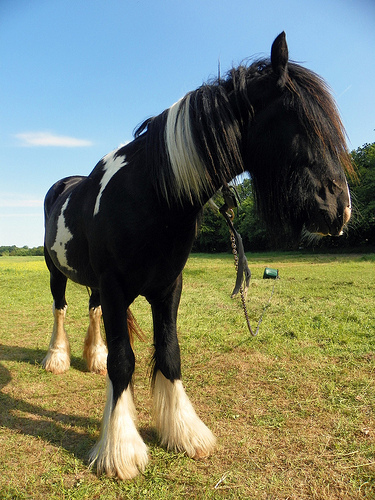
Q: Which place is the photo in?
A: It is at the field.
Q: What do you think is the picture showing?
A: It is showing a field.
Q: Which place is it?
A: It is a field.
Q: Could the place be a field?
A: Yes, it is a field.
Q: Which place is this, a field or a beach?
A: It is a field.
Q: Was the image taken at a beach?
A: No, the picture was taken in a field.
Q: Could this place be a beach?
A: No, it is a field.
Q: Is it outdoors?
A: Yes, it is outdoors.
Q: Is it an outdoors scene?
A: Yes, it is outdoors.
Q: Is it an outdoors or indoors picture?
A: It is outdoors.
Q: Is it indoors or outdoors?
A: It is outdoors.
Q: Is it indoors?
A: No, it is outdoors.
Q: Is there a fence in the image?
A: No, there are no fences.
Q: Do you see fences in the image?
A: No, there are no fences.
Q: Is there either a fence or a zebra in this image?
A: No, there are no fences or zebras.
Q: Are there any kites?
A: No, there are no kites.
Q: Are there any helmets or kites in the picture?
A: No, there are no kites or helmets.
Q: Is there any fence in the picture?
A: No, there are no fences.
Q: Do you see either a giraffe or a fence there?
A: No, there are no fences or giraffes.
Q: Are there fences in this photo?
A: No, there are no fences.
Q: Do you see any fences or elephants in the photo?
A: No, there are no fences or elephants.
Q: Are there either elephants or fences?
A: No, there are no fences or elephants.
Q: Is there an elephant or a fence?
A: No, there are no fences or elephants.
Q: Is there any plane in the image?
A: No, there are no airplanes.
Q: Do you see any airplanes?
A: No, there are no airplanes.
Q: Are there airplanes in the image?
A: No, there are no airplanes.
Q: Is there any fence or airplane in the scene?
A: No, there are no airplanes or fences.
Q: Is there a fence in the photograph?
A: No, there are no fences.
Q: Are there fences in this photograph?
A: No, there are no fences.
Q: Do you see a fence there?
A: No, there are no fences.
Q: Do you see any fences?
A: No, there are no fences.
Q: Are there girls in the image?
A: No, there are no girls.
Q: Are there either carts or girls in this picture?
A: No, there are no girls or carts.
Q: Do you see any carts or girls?
A: No, there are no girls or carts.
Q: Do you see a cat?
A: No, there are no cats.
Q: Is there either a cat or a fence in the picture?
A: No, there are no cats or fences.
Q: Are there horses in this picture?
A: Yes, there is a horse.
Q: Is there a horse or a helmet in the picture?
A: Yes, there is a horse.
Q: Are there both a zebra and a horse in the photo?
A: No, there is a horse but no zebras.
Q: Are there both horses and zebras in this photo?
A: No, there is a horse but no zebras.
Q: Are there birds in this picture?
A: No, there are no birds.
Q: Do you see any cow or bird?
A: No, there are no birds or cows.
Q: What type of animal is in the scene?
A: The animal is a horse.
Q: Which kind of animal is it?
A: The animal is a horse.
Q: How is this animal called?
A: This is a horse.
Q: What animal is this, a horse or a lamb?
A: This is a horse.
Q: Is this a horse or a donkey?
A: This is a horse.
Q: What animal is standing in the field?
A: The horse is standing in the field.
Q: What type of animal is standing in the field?
A: The animal is a horse.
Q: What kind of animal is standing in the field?
A: The animal is a horse.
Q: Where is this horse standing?
A: The horse is standing in the field.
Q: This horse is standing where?
A: The horse is standing in the field.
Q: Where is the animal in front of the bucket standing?
A: The horse is standing in the field.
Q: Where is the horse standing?
A: The horse is standing in the field.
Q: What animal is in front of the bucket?
A: The horse is in front of the bucket.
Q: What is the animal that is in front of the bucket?
A: The animal is a horse.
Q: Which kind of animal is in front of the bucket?
A: The animal is a horse.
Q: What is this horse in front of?
A: The horse is in front of the bucket.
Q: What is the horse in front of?
A: The horse is in front of the bucket.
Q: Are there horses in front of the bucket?
A: Yes, there is a horse in front of the bucket.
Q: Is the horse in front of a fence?
A: No, the horse is in front of the bucket.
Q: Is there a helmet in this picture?
A: No, there are no helmets.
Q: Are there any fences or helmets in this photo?
A: No, there are no helmets or fences.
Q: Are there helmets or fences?
A: No, there are no helmets or fences.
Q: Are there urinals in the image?
A: No, there are no urinals.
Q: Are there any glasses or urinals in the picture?
A: No, there are no urinals or glasses.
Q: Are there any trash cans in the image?
A: No, there are no trash cans.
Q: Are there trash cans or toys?
A: No, there are no trash cans or toys.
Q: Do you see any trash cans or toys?
A: No, there are no trash cans or toys.